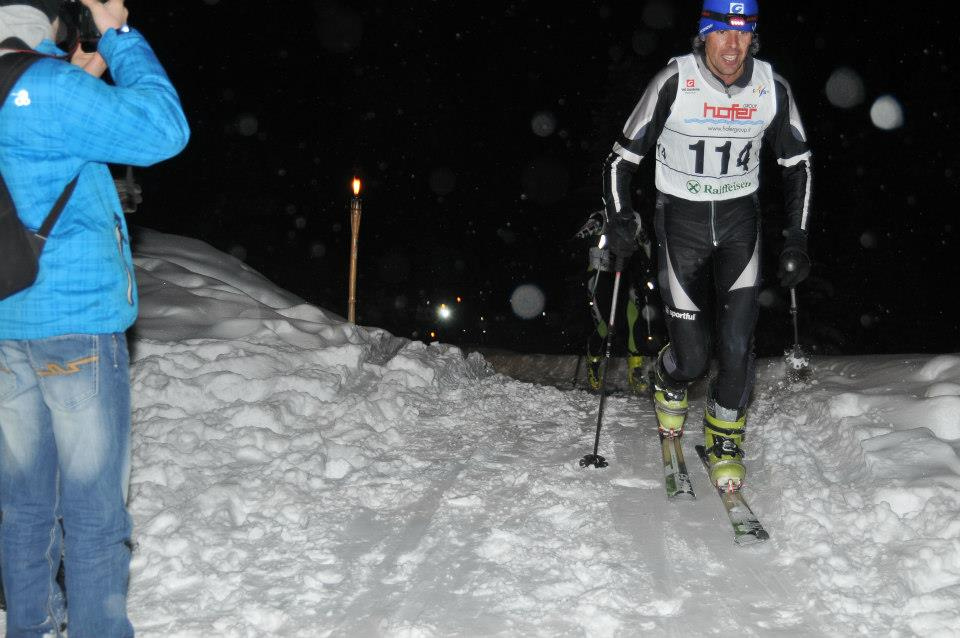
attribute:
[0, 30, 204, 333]
jacket — blue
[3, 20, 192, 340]
jacket — blue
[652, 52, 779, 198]
jersey — white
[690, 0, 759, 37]
hat — blue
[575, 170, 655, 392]
person — skiing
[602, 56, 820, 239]
jacket — blue and gray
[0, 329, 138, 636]
jeans — blue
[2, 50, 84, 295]
backpack — black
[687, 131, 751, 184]
number — black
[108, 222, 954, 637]
snow — white